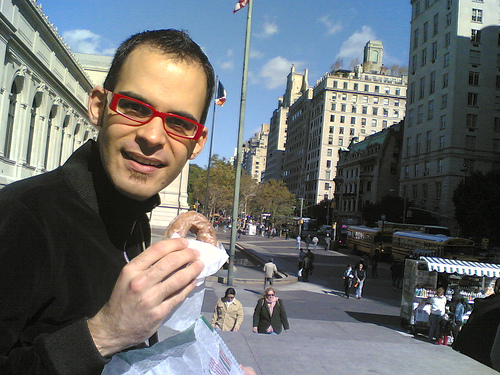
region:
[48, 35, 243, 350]
a man eating a doughnut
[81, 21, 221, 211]
the head of an adult man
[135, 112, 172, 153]
the nose of an adult man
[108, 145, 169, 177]
the mouth of an adult man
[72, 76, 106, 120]
the ear of an adult man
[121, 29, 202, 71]
the hair of an adult man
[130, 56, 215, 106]
the forehead of an adult man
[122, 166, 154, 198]
the beard of an adult man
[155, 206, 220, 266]
a freshly made glazed doughnut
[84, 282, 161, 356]
the wrist of an adult man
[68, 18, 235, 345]
a man holding a doughnut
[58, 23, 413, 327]
a man in front of a city street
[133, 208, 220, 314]
a hand holding a doughnut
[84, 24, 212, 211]
a man wearing red glasses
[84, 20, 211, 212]
a man who is smiling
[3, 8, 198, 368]
a man who is wearing a black jacket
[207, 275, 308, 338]
two women walking up stairs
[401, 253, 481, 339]
two people standing at a food truck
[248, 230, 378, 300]
people on a city street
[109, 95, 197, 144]
he is wearing glasses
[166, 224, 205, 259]
he is holding a donut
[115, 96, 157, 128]
the glasses are red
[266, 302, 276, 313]
the shirt is pink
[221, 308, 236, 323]
the coat is tan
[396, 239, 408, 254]
the bus is yellow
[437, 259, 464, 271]
the awning is striped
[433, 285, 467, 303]
they are ordering from the food vender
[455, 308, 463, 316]
the coat is blue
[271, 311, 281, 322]
the coat is black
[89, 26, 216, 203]
Man wearing red glasses.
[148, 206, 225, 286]
Donut with donut hole.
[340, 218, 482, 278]
Two school busses on the road.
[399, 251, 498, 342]
Hotdog stand at side of road.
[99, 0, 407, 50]
Forecast is partly cloudy with blue skies.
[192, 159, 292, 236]
Green trees between buildings.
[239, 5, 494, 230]
Multiple high rise buildings.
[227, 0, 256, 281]
Tall light post.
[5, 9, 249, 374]
Man holding donut in right hand.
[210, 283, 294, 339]
Two people wearing heavy coats.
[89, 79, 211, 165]
the man is wearing red glasses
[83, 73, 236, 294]
the man has a donut in his hand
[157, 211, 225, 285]
a napkin is around the donut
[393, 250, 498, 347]
a cart is by the street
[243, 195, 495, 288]
buses are lined up streetside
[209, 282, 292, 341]
the ladies are wearing coats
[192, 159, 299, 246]
trees are on the sidewalk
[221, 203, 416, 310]
people are walking on the wide sidewalk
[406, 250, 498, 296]
the awning on the cart is striped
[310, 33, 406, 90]
a tower is on top of the building